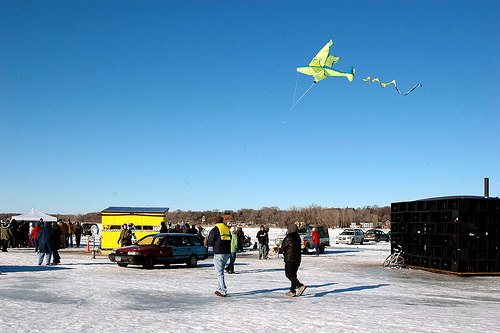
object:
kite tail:
[361, 75, 422, 96]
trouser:
[214, 253, 229, 295]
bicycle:
[382, 245, 405, 270]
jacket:
[278, 232, 301, 262]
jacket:
[207, 223, 231, 254]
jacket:
[311, 230, 319, 244]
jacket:
[37, 223, 54, 253]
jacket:
[231, 231, 238, 253]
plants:
[327, 204, 350, 229]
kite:
[296, 39, 422, 97]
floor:
[279, 91, 401, 136]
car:
[335, 229, 364, 245]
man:
[207, 215, 232, 297]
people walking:
[0, 199, 320, 298]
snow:
[0, 224, 500, 333]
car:
[109, 233, 209, 269]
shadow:
[303, 284, 391, 298]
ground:
[0, 227, 500, 333]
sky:
[0, 0, 500, 215]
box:
[390, 196, 499, 278]